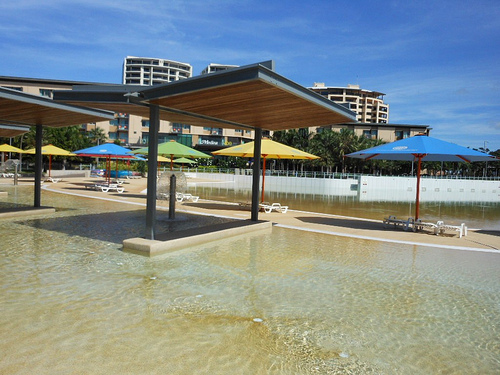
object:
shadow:
[14, 208, 279, 242]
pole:
[415, 157, 421, 219]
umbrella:
[343, 132, 499, 162]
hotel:
[157, 112, 257, 172]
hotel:
[42, 111, 152, 172]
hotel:
[1, 72, 133, 102]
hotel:
[1, 120, 36, 187]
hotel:
[257, 120, 433, 172]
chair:
[96, 186, 125, 193]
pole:
[168, 173, 176, 219]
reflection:
[184, 162, 359, 204]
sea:
[363, 238, 401, 270]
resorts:
[0, 55, 499, 367]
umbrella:
[211, 136, 321, 159]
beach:
[0, 168, 498, 373]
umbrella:
[129, 140, 212, 158]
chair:
[382, 215, 468, 239]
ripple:
[220, 352, 245, 369]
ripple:
[148, 345, 194, 374]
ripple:
[266, 351, 281, 372]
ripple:
[301, 319, 310, 349]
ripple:
[450, 297, 461, 318]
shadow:
[292, 216, 458, 238]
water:
[97, 202, 289, 284]